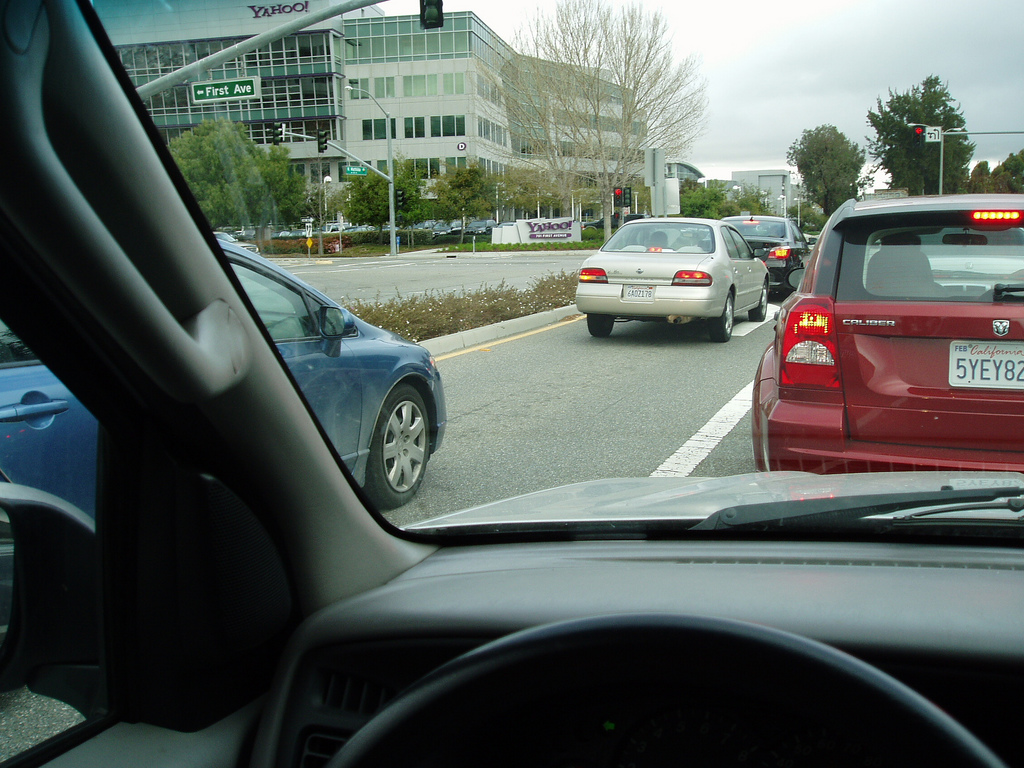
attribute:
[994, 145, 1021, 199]
tree — green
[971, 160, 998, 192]
tree — green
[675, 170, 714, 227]
tree — green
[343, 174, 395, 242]
tree — green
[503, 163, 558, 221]
tree — green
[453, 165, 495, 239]
tree — green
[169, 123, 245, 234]
tree — green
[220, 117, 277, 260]
tree — green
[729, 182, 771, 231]
tree — green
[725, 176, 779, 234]
tree — green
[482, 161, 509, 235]
tree — green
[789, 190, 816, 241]
tree — green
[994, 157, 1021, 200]
tree — green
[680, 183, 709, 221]
tree — green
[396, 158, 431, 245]
tree — green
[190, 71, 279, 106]
street sign — green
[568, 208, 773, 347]
car — red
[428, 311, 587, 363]
line — yellow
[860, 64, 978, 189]
tree — tall, green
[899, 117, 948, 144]
street light — red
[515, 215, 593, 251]
sign — white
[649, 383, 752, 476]
line — white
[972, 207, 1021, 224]
mini lights — red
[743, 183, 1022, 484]
car — red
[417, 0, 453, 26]
light — black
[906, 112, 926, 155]
light — black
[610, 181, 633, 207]
light — black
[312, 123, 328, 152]
light — black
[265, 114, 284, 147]
light — black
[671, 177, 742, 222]
leaves — green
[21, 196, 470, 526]
car — blue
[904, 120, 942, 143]
traffic sign — black, white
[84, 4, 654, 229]
building — white, large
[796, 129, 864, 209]
leaves — green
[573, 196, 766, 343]
car — small